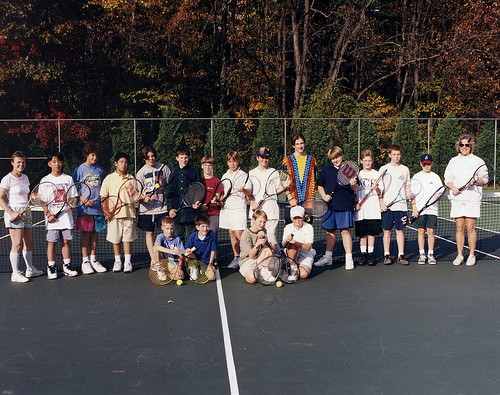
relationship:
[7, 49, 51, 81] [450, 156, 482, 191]
leaves wearing shirt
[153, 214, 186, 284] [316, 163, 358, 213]
boy wearing shirt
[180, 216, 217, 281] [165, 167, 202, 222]
boy wearing shirt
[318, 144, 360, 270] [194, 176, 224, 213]
boy wearing shirt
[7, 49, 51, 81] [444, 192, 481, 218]
leaves wearing skirt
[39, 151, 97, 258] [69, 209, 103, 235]
kid wearing shorts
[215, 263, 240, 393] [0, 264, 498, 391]
stripe on floor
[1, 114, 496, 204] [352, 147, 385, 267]
fence behind person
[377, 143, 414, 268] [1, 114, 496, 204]
person behind fence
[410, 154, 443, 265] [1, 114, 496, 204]
boy behind fence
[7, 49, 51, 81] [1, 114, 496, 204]
leaves behind fence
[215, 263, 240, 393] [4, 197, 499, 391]
stripe on court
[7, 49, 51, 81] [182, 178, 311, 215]
leaves holding rackets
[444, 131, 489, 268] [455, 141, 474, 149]
lady wearing sunglasses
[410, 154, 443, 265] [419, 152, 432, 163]
boy wearing hat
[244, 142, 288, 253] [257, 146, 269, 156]
boy wearing hat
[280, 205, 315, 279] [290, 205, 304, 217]
boy wearing hat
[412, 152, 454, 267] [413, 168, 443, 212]
boy wearing shirt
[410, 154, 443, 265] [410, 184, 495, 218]
boy wearing racket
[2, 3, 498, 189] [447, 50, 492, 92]
trees with leaves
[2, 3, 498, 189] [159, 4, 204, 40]
trees with leaves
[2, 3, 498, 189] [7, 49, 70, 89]
trees with leaves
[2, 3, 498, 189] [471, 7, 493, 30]
trees with leaves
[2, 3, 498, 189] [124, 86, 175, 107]
trees with leaves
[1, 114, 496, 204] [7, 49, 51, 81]
fence behind leaves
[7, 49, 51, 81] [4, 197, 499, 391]
leaves standing on court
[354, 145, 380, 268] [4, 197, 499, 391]
person standing on court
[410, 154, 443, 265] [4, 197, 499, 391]
boy standing on court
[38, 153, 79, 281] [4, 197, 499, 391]
kid standing on court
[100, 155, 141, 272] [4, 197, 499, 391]
boy standing on court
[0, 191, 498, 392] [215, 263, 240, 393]
tennis court with stripe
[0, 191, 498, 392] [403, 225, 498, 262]
tennis court with stripe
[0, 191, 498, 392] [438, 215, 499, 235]
tennis court with stripe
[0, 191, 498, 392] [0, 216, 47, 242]
tennis court with stripe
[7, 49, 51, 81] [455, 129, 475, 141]
leaves has hair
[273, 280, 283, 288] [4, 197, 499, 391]
ball lies on court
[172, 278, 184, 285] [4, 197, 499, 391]
ball lies on court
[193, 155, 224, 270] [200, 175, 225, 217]
boy in shirt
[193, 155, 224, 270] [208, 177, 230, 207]
boy holds racket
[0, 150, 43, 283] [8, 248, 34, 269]
kid wearing socks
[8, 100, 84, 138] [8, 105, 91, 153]
tree has foliage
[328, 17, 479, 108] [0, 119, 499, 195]
branches behind fence